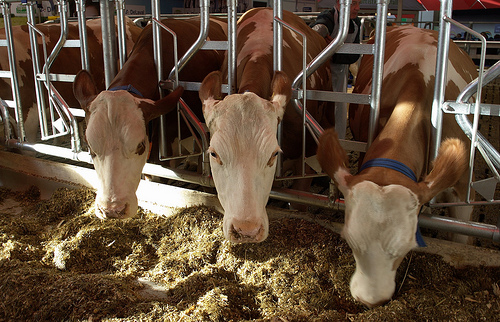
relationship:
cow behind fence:
[67, 15, 206, 231] [5, 1, 490, 109]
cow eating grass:
[196, 69, 295, 248] [0, 189, 500, 321]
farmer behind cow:
[312, 0, 366, 152] [196, 69, 295, 248]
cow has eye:
[67, 15, 206, 231] [132, 142, 150, 156]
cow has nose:
[196, 69, 295, 248] [223, 216, 273, 245]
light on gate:
[35, 89, 91, 157] [21, 3, 194, 172]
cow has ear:
[316, 126, 470, 307] [317, 128, 347, 188]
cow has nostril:
[67, 15, 206, 231] [118, 201, 135, 217]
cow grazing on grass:
[316, 126, 470, 307] [333, 291, 408, 321]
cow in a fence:
[316, 126, 470, 307] [0, 1, 500, 242]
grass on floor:
[333, 291, 408, 321] [32, 250, 276, 322]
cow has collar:
[67, 15, 206, 231] [107, 84, 149, 100]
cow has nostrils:
[196, 69, 295, 248] [228, 217, 267, 244]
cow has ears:
[196, 69, 295, 248] [198, 68, 292, 106]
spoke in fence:
[150, 1, 162, 167] [5, 1, 490, 109]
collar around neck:
[360, 158, 420, 181] [359, 122, 435, 187]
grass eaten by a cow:
[333, 291, 408, 321] [67, 15, 206, 231]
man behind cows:
[312, 0, 366, 152] [66, 28, 485, 314]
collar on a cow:
[360, 158, 420, 181] [67, 15, 206, 231]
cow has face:
[196, 69, 295, 248] [208, 130, 280, 247]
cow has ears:
[67, 15, 206, 231] [69, 69, 182, 122]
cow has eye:
[196, 69, 295, 248] [206, 150, 222, 163]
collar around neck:
[107, 84, 149, 100] [117, 60, 157, 98]